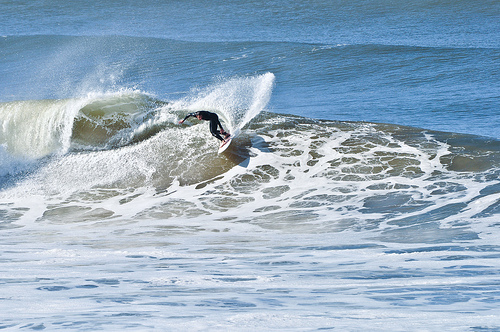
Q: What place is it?
A: It is an ocean.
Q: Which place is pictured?
A: It is an ocean.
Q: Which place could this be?
A: It is an ocean.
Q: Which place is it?
A: It is an ocean.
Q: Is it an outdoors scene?
A: Yes, it is outdoors.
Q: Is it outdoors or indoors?
A: It is outdoors.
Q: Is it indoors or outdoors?
A: It is outdoors.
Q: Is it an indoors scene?
A: No, it is outdoors.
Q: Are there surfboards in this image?
A: Yes, there is a surfboard.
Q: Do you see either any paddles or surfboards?
A: Yes, there is a surfboard.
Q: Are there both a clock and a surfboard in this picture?
A: No, there is a surfboard but no clocks.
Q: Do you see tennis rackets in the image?
A: No, there are no tennis rackets.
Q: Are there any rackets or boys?
A: No, there are no rackets or boys.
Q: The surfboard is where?
A: The surfboard is on the ocean.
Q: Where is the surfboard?
A: The surfboard is on the ocean.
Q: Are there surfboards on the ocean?
A: Yes, there is a surfboard on the ocean.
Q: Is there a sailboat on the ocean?
A: No, there is a surfboard on the ocean.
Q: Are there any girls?
A: No, there are no girls.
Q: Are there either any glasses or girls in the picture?
A: No, there are no girls or glasses.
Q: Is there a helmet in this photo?
A: No, there are no helmets.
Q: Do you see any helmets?
A: No, there are no helmets.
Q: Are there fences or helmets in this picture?
A: No, there are no helmets or fences.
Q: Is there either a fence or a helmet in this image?
A: No, there are no helmets or fences.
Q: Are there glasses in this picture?
A: No, there are no glasses.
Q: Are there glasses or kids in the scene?
A: No, there are no glasses or kids.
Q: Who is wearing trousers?
A: The man is wearing trousers.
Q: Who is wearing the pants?
A: The man is wearing trousers.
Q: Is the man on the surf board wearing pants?
A: Yes, the man is wearing pants.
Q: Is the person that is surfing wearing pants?
A: Yes, the man is wearing pants.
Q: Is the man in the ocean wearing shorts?
A: No, the man is wearing pants.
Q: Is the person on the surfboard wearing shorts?
A: No, the man is wearing pants.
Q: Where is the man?
A: The man is in the ocean.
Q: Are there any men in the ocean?
A: Yes, there is a man in the ocean.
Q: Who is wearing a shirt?
A: The man is wearing a shirt.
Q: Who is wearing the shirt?
A: The man is wearing a shirt.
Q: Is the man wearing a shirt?
A: Yes, the man is wearing a shirt.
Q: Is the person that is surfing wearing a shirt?
A: Yes, the man is wearing a shirt.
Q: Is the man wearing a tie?
A: No, the man is wearing a shirt.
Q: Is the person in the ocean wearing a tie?
A: No, the man is wearing a shirt.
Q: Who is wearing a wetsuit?
A: The man is wearing a wetsuit.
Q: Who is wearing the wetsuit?
A: The man is wearing a wetsuit.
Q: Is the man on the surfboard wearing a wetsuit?
A: Yes, the man is wearing a wetsuit.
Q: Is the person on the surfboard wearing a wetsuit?
A: Yes, the man is wearing a wetsuit.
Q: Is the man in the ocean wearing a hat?
A: No, the man is wearing a wetsuit.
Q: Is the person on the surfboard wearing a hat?
A: No, the man is wearing a wetsuit.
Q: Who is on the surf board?
A: The man is on the surf board.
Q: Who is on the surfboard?
A: The man is on the surf board.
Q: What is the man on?
A: The man is on the surf board.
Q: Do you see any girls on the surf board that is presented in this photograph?
A: No, there is a man on the surf board.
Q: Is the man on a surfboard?
A: Yes, the man is on a surfboard.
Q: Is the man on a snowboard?
A: No, the man is on a surfboard.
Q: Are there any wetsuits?
A: Yes, there is a wetsuit.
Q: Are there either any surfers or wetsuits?
A: Yes, there is a wetsuit.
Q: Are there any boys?
A: No, there are no boys.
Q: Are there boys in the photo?
A: No, there are no boys.